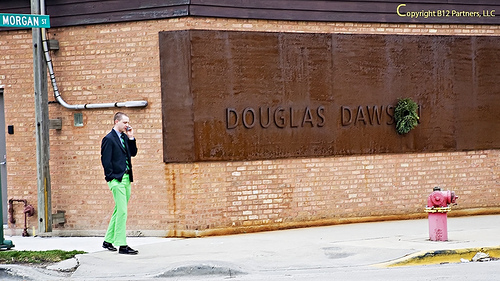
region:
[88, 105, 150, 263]
A man with green trousers on his cell phone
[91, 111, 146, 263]
A man with green trousers on his cell phone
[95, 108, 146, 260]
A man with green trousers on his cell phone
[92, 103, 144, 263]
A man with green trousers on his cell phone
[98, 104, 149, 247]
man in green pants on phone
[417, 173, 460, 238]
red faded fire extinguisher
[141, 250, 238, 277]
slope of side walk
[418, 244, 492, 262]
yellow part of sidewalk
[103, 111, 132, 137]
man talking on phone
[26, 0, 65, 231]
light power pole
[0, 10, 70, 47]
street sign for morgan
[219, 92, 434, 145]
douglas daws name of building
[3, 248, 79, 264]
slab of grass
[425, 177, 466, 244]
a red fire hydrant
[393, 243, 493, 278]
a concrete curb painted yellow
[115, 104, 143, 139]
a man using a cell phone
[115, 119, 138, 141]
a man holding a cell phone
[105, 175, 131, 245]
a man wearing green pants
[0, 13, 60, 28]
a green and white street sign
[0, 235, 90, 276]
a patch of green grass next to the road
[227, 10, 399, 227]
a red brick building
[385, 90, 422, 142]
a green wreath hanging on a building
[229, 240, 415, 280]
a handicap ramp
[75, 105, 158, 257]
THE MAN IS TALKING ON THE PHONE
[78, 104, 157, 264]
THE MAN IS ON THE SIDEWALK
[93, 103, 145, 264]
THE MAN IS WALKING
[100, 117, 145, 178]
THE MAN IS WEARING A BLACK JACKET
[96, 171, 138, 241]
THE MAN IS WEARING GREEN PANTS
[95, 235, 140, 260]
THE MAN IS WEARING BLACK SHOES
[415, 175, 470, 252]
THE HYDRANT IS RED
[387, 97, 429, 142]
THE WREATH IS ON THE WALL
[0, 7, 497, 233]
THE BUILDING IS BRICK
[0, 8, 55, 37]
THE SIGN IS GREEN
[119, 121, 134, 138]
The man is using a phone.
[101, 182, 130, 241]
The man's pants are green.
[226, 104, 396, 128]
The name Douglas Daws is on the building.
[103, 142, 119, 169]
The jacket is navy blue.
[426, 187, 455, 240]
A fire hydrant is in front of the building.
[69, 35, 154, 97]
The building is made of brick.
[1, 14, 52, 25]
The street sign reads Morgan Street.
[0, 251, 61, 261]
A patch of grass is on the sidewalk.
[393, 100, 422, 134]
A wreath is on the building.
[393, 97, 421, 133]
The wreath is green.